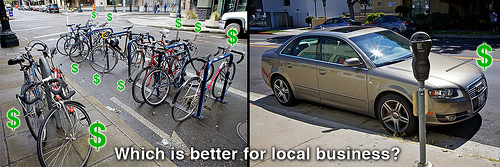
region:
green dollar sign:
[86, 118, 108, 154]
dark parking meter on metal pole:
[406, 29, 440, 165]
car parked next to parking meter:
[258, 8, 490, 144]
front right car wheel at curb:
[371, 91, 414, 163]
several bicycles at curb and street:
[9, 9, 244, 163]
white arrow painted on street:
[102, 88, 198, 160]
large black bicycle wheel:
[37, 100, 107, 165]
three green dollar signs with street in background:
[66, 60, 133, 95]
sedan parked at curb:
[256, 13, 491, 135]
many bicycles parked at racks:
[119, 16, 239, 123]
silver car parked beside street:
[257, 32, 494, 137]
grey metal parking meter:
[394, 26, 442, 164]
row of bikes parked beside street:
[11, 11, 238, 164]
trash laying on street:
[98, 94, 130, 118]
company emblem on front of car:
[465, 79, 494, 101]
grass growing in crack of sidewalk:
[437, 142, 499, 164]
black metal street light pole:
[0, 0, 27, 49]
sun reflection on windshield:
[362, 37, 400, 64]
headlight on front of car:
[426, 82, 459, 112]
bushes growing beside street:
[421, 8, 491, 32]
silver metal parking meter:
[405, 27, 432, 162]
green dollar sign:
[470, 32, 497, 77]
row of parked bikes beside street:
[7, 15, 248, 164]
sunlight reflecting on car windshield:
[357, 32, 396, 68]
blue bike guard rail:
[197, 51, 237, 124]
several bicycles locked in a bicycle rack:
[59, 16, 244, 111]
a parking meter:
[411, 31, 435, 165]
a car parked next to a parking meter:
[259, 21, 494, 131]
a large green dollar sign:
[471, 41, 493, 72]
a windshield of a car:
[369, 35, 404, 59]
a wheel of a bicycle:
[35, 100, 95, 165]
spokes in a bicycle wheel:
[48, 137, 74, 164]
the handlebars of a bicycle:
[17, 75, 74, 104]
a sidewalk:
[274, 112, 365, 143]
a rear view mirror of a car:
[344, 57, 361, 68]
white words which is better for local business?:
[111, 139, 409, 163]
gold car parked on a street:
[262, 11, 482, 132]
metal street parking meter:
[403, 23, 442, 164]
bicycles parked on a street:
[54, 9, 240, 121]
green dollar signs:
[59, 52, 157, 107]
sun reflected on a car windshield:
[351, 26, 403, 70]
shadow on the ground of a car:
[256, 85, 453, 149]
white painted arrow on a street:
[108, 85, 198, 160]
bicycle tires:
[125, 66, 223, 124]